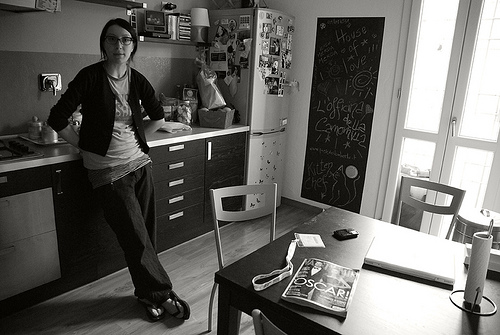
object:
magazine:
[279, 255, 361, 317]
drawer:
[2, 108, 249, 173]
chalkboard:
[300, 18, 387, 216]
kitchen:
[1, 2, 497, 332]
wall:
[266, 3, 423, 226]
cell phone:
[334, 231, 367, 244]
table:
[227, 209, 457, 333]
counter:
[0, 121, 250, 172]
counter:
[151, 119, 209, 239]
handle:
[444, 118, 458, 139]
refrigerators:
[207, 8, 299, 210]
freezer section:
[237, 135, 288, 215]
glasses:
[101, 33, 117, 43]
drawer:
[162, 142, 197, 164]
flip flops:
[117, 276, 216, 325]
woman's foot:
[160, 296, 182, 320]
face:
[103, 21, 133, 62]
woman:
[50, 18, 190, 322]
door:
[373, 0, 497, 230]